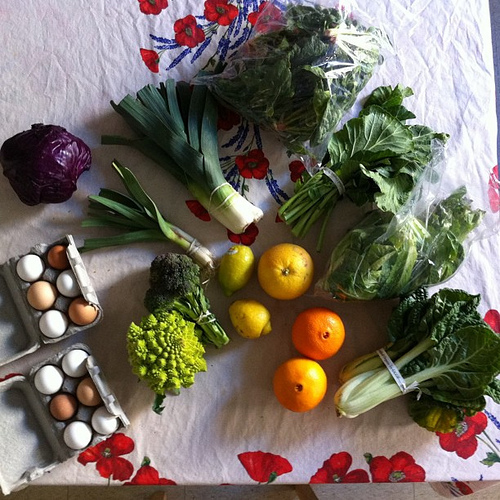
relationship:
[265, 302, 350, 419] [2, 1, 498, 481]
navel oranges on table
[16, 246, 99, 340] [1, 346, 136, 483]
eggs in carton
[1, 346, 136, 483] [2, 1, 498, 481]
carton on table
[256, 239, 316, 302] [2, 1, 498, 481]
grapefruit on table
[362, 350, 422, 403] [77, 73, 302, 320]
rubber band on leeks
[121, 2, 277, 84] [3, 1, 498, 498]
poppies on tablecloth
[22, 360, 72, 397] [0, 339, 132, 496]
egg in carton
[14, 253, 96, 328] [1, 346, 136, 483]
eggs in carton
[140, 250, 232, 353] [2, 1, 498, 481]
broccoli on table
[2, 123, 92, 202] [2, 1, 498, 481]
cabbage on table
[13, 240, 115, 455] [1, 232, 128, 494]
eggs on two cartons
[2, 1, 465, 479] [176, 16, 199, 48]
cloth has flowers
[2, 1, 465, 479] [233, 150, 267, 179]
cloth has flowers